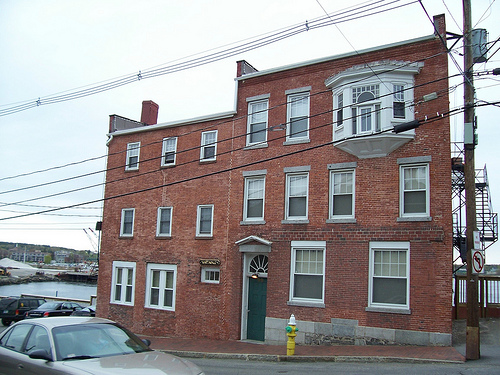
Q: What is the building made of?
A: Brick.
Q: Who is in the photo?
A: Nobody.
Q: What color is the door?
A: Green.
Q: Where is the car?
A: Parked on the street.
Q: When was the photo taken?
A: Daytime.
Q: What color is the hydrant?
A: Yellow.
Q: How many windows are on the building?
A: Eighteen.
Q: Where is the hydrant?
A: On the sidewalk.